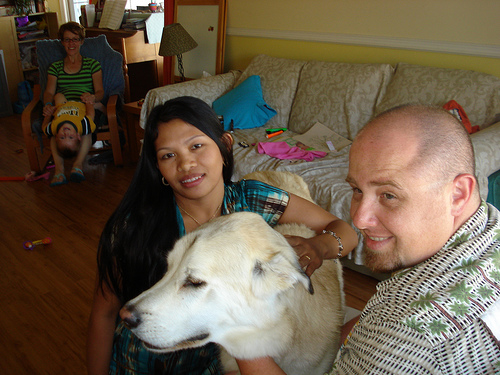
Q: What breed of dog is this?
A: Great pyrenees.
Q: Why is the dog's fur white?
A: Genetics.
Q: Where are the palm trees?
A: On the man's shirt.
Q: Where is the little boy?
A: In his mom's arms.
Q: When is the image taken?
A: People holding dog.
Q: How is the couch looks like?
A: Good.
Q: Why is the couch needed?
A: Sit.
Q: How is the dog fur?
A: Smooth.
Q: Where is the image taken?
A: Living room.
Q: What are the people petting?
A: A dog.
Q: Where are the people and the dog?
A: In a house.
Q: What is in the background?
A: A couch.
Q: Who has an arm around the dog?
A: The woman in plaid.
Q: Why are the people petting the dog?
A: It is a good dog.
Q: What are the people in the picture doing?
A: Petting a dog.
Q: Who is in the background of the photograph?
A: A woman and a toddler.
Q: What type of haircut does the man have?
A: A buzz cut.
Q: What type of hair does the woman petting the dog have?
A: Long and dark.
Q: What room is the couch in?
A: The living room.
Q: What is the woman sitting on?
A: A rocking chair.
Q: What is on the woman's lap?
A: An upside down child.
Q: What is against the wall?
A: A white sofa.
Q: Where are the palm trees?
A: On the man's shirt.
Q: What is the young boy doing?
A: Leaning back.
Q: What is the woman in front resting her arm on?
A: Dog.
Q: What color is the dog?
A: White.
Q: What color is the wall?
A: Yellow.